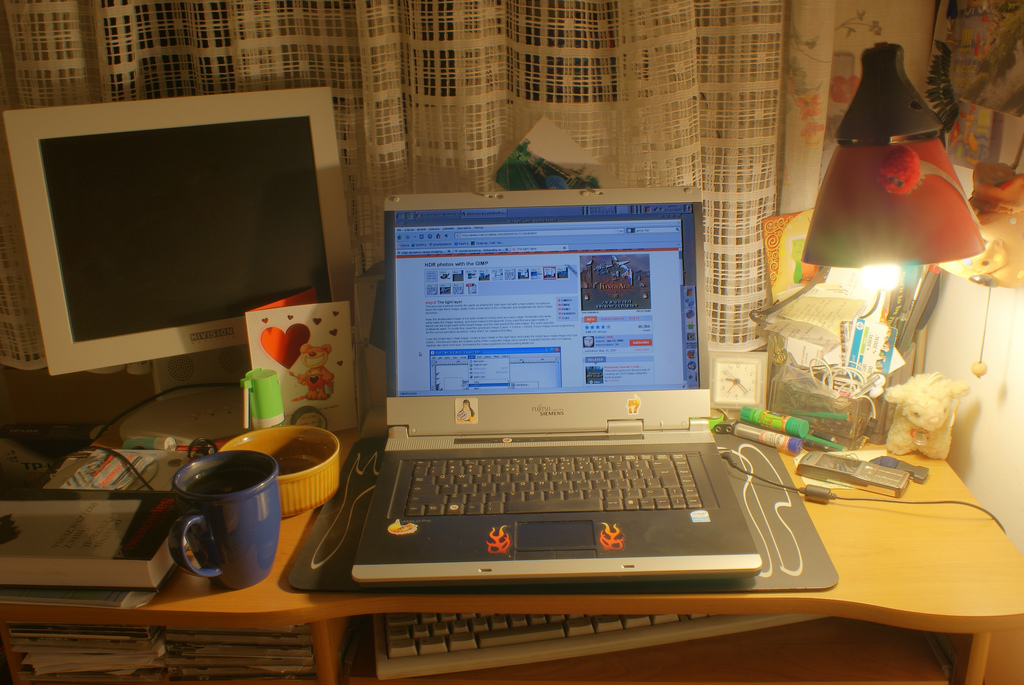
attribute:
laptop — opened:
[345, 184, 761, 592]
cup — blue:
[171, 444, 293, 603]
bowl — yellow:
[222, 424, 356, 529]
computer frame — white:
[3, 86, 370, 374]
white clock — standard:
[705, 348, 772, 412]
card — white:
[247, 297, 372, 431]